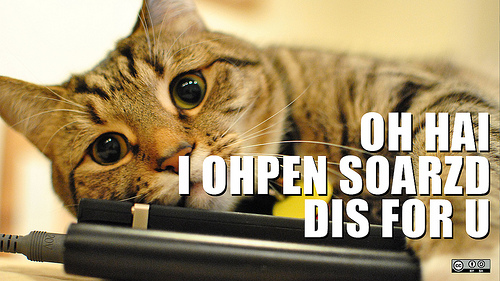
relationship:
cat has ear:
[2, 1, 492, 280] [0, 75, 64, 157]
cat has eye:
[2, 1, 492, 280] [169, 67, 207, 109]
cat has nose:
[2, 1, 492, 280] [147, 130, 195, 175]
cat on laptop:
[2, 1, 492, 280] [66, 200, 423, 281]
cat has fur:
[2, 1, 492, 280] [4, 0, 500, 281]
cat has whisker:
[2, 1, 492, 280] [234, 140, 384, 160]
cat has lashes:
[2, 1, 492, 280] [15, 90, 95, 155]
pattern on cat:
[74, 45, 166, 126] [2, 1, 492, 280]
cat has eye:
[2, 1, 492, 280] [86, 131, 134, 165]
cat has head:
[2, 1, 492, 280] [0, 1, 290, 218]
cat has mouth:
[2, 1, 492, 280] [178, 179, 205, 206]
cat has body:
[2, 1, 492, 280] [267, 44, 499, 281]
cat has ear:
[2, 1, 492, 280] [133, 0, 211, 32]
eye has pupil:
[169, 67, 207, 109] [176, 78, 202, 104]